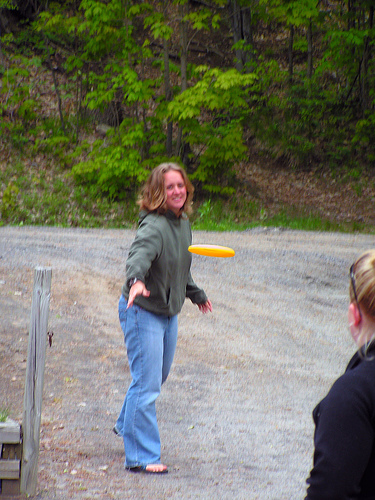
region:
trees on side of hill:
[2, 2, 372, 220]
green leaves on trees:
[4, 0, 372, 204]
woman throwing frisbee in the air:
[113, 162, 234, 472]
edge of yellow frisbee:
[188, 243, 235, 258]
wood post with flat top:
[21, 265, 51, 497]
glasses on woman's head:
[350, 247, 372, 345]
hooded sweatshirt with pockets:
[122, 206, 203, 313]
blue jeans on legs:
[117, 293, 178, 473]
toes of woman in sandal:
[131, 462, 171, 472]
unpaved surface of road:
[3, 226, 372, 497]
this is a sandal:
[145, 443, 186, 490]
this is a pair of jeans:
[129, 431, 152, 459]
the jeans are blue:
[81, 394, 230, 467]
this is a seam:
[128, 406, 142, 428]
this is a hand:
[120, 277, 180, 322]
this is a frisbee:
[195, 237, 233, 274]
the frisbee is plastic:
[192, 244, 216, 279]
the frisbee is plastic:
[185, 241, 231, 265]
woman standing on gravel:
[102, 158, 220, 486]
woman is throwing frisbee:
[106, 154, 218, 481]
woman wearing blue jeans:
[106, 287, 184, 484]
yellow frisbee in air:
[185, 239, 233, 270]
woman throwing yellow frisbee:
[181, 235, 236, 263]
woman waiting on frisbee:
[290, 242, 373, 498]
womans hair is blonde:
[347, 246, 374, 364]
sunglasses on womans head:
[347, 256, 362, 322]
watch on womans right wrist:
[124, 274, 141, 286]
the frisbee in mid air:
[187, 244, 234, 256]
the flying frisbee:
[187, 244, 234, 256]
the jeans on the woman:
[114, 294, 177, 468]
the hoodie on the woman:
[120, 206, 206, 315]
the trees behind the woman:
[0, 0, 371, 200]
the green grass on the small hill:
[0, 118, 373, 233]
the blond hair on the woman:
[136, 161, 194, 219]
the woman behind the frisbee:
[113, 163, 212, 473]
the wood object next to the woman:
[0, 266, 53, 495]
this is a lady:
[113, 165, 194, 475]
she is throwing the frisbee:
[112, 229, 164, 304]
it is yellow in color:
[184, 240, 239, 263]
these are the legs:
[108, 315, 173, 439]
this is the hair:
[137, 179, 165, 206]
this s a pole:
[24, 268, 56, 330]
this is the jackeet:
[153, 228, 179, 276]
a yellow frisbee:
[187, 243, 234, 258]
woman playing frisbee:
[117, 163, 212, 473]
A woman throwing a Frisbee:
[117, 154, 238, 321]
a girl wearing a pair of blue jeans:
[114, 151, 228, 374]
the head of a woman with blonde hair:
[335, 243, 373, 345]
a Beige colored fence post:
[21, 260, 55, 491]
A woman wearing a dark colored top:
[302, 247, 372, 493]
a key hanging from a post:
[39, 320, 57, 350]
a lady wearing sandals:
[112, 158, 210, 478]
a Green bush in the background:
[194, 62, 281, 223]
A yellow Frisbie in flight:
[178, 235, 241, 265]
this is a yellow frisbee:
[172, 231, 254, 278]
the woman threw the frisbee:
[99, 124, 255, 477]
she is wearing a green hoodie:
[91, 134, 231, 343]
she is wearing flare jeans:
[79, 278, 206, 485]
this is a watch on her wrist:
[116, 265, 148, 291]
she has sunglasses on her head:
[319, 245, 373, 333]